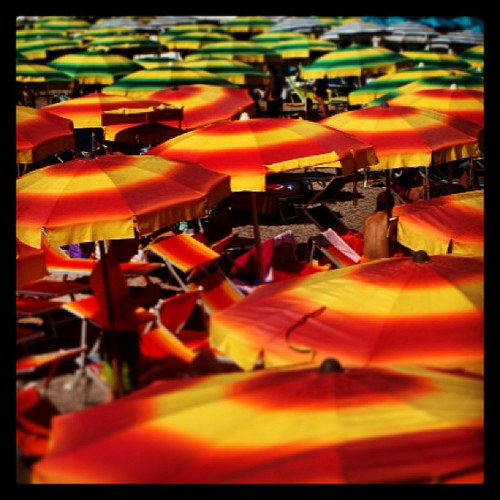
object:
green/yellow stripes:
[83, 52, 263, 84]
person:
[264, 63, 286, 116]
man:
[90, 239, 160, 392]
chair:
[265, 228, 318, 284]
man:
[359, 189, 400, 261]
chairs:
[305, 204, 359, 245]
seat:
[150, 234, 221, 292]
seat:
[15, 249, 87, 299]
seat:
[147, 285, 209, 351]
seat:
[91, 314, 159, 373]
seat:
[308, 206, 396, 260]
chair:
[290, 173, 345, 212]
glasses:
[119, 240, 139, 249]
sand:
[221, 82, 421, 262]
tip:
[316, 358, 343, 378]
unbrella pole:
[96, 240, 125, 395]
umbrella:
[12, 13, 481, 485]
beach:
[12, 17, 482, 486]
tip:
[237, 111, 250, 122]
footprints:
[349, 212, 358, 222]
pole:
[248, 191, 265, 283]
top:
[33, 357, 485, 482]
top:
[330, 103, 465, 166]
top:
[176, 111, 331, 175]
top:
[316, 41, 369, 73]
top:
[0, 154, 205, 235]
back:
[363, 212, 393, 259]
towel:
[265, 232, 314, 279]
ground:
[14, 132, 497, 422]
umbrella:
[16, 138, 226, 259]